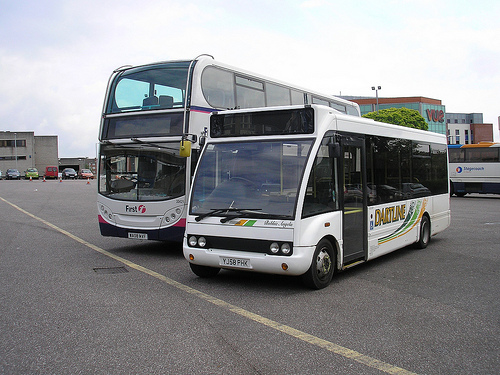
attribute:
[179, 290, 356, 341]
line — yellow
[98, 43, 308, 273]
bus — double decker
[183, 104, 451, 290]
bus — white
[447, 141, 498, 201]
bus — white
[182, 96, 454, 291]
van — red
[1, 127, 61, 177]
building — tan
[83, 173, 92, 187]
cone — orange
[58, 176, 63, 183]
cone — orange